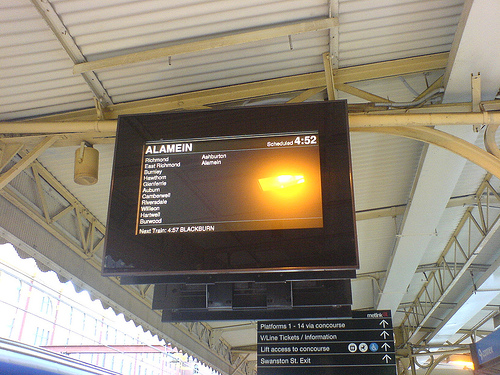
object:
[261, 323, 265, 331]
letters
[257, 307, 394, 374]
directional sign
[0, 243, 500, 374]
platform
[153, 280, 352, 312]
sign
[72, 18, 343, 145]
frame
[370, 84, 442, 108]
pipe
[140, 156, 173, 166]
writing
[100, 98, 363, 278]
black television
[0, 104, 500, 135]
yellow-metal bar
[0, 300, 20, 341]
building windows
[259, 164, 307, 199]
light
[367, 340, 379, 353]
blue-handicapped logo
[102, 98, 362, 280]
travel marquee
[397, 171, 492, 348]
ceiling supports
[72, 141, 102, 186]
white-tubular light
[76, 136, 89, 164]
metal mount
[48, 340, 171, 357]
red-metal beam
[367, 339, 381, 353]
blue-handicap sticker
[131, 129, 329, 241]
monitor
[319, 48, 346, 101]
white-metal mounts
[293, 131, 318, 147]
digital-time displayed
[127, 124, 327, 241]
screen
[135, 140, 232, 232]
train schedule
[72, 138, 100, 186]
light fixture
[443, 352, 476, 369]
light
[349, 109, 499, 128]
pipe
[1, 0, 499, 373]
building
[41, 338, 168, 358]
girder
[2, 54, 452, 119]
beam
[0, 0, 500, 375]
roof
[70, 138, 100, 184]
can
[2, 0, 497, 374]
ceiling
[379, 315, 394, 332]
arrows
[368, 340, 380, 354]
circle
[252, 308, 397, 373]
sign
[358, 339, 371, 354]
circle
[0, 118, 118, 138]
pipe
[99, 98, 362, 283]
board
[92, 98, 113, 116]
bracket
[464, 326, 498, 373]
sign